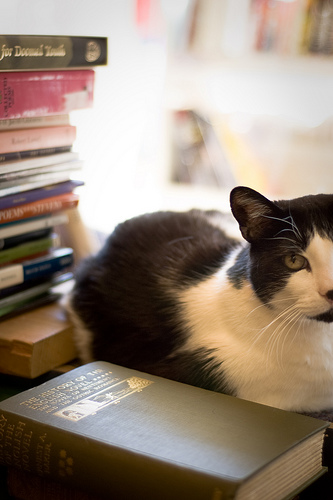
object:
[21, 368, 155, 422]
title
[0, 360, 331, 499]
book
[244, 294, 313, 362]
whiskers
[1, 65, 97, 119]
red book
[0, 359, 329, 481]
book cover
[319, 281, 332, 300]
nose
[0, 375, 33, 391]
shelf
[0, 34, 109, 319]
book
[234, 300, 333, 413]
white chest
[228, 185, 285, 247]
ear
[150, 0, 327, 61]
shelf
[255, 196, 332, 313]
face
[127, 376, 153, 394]
gold leaf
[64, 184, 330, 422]
cat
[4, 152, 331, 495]
forward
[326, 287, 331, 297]
tip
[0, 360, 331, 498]
cover